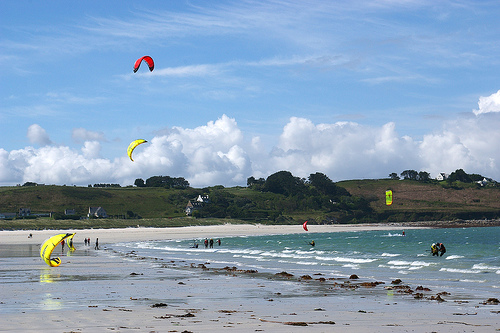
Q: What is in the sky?
A: Kites.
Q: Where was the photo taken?
A: The beach.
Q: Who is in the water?
A: Beachgoers.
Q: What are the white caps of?
A: Crashed waves.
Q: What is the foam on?
A: Surface of ocean water.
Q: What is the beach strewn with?
A: Seaweed.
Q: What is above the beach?
A: Grass covered hill.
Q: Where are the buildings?
A: By the sandy beach.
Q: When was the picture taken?
A: Morning.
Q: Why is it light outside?
A: Sunny.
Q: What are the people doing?
A: Playing.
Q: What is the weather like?
A: Cloudy.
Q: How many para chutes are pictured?
A: 4.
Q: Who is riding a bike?
A: Nobody.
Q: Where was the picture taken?
A: Beach.